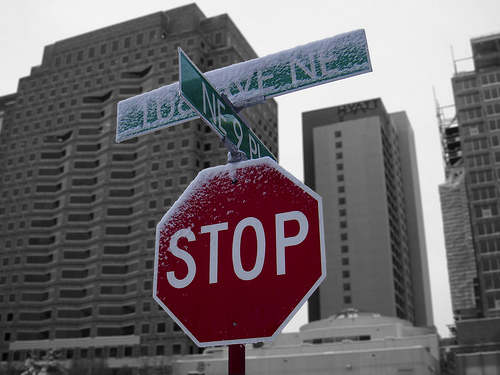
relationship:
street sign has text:
[177, 46, 277, 163] [201, 81, 261, 160]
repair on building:
[437, 43, 482, 321] [430, 30, 498, 374]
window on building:
[333, 129, 342, 138] [301, 98, 417, 325]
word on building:
[336, 97, 379, 117] [301, 98, 417, 325]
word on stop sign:
[166, 209, 308, 289] [151, 155, 328, 350]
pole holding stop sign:
[228, 151, 247, 375] [151, 155, 328, 350]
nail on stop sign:
[231, 176, 237, 185] [151, 155, 328, 350]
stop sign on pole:
[151, 155, 328, 350] [228, 151, 247, 375]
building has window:
[0, 7, 279, 374] [110, 169, 137, 180]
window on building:
[333, 129, 342, 138] [0, 7, 279, 374]